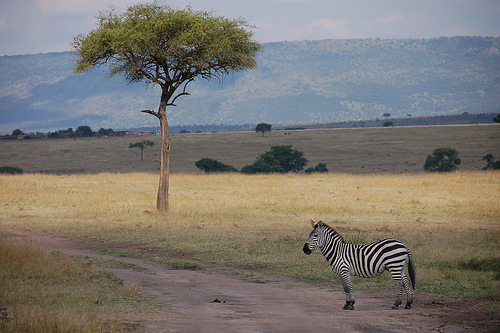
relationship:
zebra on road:
[296, 214, 419, 313] [12, 203, 474, 331]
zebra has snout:
[296, 214, 419, 313] [300, 243, 314, 265]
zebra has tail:
[296, 214, 419, 313] [401, 252, 422, 288]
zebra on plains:
[296, 214, 419, 313] [4, 2, 496, 333]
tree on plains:
[63, 0, 259, 217] [4, 2, 496, 333]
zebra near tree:
[296, 214, 419, 313] [63, 0, 259, 217]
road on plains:
[12, 203, 474, 331] [4, 2, 496, 333]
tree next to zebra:
[63, 0, 259, 217] [296, 214, 419, 313]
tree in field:
[63, 0, 259, 217] [10, 168, 499, 325]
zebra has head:
[296, 214, 419, 313] [300, 216, 336, 265]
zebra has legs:
[296, 214, 419, 313] [340, 267, 419, 328]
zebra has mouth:
[296, 214, 419, 313] [307, 242, 314, 258]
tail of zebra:
[401, 252, 422, 288] [296, 214, 419, 313]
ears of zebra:
[310, 219, 327, 231] [296, 214, 419, 313]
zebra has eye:
[296, 214, 419, 313] [315, 232, 321, 241]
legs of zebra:
[340, 267, 419, 328] [296, 214, 419, 313]